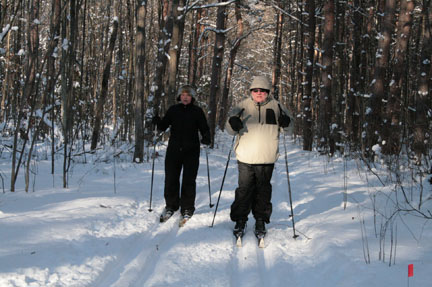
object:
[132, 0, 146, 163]
trunk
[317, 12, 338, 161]
tree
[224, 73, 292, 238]
person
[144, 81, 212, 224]
person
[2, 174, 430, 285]
snow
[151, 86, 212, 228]
people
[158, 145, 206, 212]
pants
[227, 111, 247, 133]
gloves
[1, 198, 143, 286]
white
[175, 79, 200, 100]
hats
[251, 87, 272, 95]
sunglasses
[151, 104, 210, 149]
jacket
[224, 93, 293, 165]
jacket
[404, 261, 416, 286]
flag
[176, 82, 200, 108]
head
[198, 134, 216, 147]
glove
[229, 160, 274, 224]
pants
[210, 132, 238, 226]
ski poles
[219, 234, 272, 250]
skis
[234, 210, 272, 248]
ski boots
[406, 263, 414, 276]
red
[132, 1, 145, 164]
trees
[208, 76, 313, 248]
skiing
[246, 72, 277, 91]
hat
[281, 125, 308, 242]
ski poles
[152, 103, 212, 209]
black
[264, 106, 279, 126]
pocket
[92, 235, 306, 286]
paths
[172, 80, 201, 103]
hat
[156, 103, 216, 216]
snow suit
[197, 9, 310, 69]
sunshine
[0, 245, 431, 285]
ground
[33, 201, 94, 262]
snow